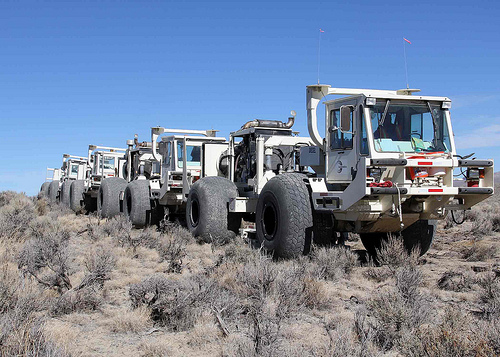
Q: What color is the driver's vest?
A: Orange.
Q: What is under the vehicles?
A: Sand.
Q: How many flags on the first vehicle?
A: Two.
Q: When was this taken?
A: During the daytime.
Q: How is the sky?
A: Clear.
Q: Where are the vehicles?
A: A desert.